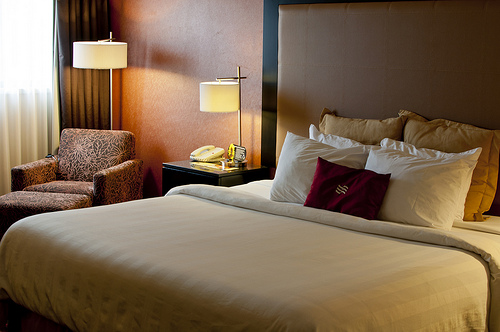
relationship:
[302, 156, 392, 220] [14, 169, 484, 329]
pillow on bed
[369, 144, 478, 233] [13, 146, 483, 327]
pillow on bed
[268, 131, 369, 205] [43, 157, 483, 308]
pillow on bed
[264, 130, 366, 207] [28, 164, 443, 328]
pillow on bed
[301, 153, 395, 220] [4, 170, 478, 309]
pillow on bed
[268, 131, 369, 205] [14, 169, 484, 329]
pillow on bed